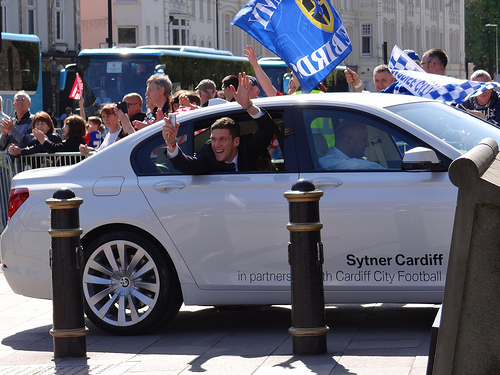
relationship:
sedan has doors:
[1, 93, 500, 335] [130, 99, 306, 292]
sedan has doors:
[1, 93, 500, 335] [301, 102, 460, 292]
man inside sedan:
[162, 71, 289, 176] [1, 93, 500, 335]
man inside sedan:
[318, 119, 389, 171] [1, 93, 500, 335]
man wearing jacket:
[162, 71, 289, 176] [166, 113, 281, 171]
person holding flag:
[243, 43, 303, 96] [229, 0, 354, 96]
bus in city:
[73, 44, 350, 118] [1, 2, 497, 374]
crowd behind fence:
[3, 59, 500, 146] [3, 153, 95, 236]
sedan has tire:
[1, 93, 500, 335] [78, 227, 184, 336]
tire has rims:
[78, 227, 184, 336] [81, 241, 160, 327]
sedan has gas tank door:
[1, 93, 500, 335] [90, 174, 126, 199]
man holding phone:
[162, 71, 289, 176] [166, 112, 176, 128]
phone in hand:
[166, 112, 176, 128] [160, 118, 181, 148]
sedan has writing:
[1, 93, 500, 335] [236, 252, 446, 284]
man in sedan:
[318, 119, 389, 171] [1, 93, 500, 335]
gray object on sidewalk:
[425, 138, 498, 374] [2, 360, 497, 374]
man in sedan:
[162, 71, 289, 176] [1, 93, 500, 335]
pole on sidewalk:
[46, 187, 91, 365] [2, 360, 497, 374]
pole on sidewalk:
[283, 179, 331, 356] [2, 360, 497, 374]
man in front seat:
[318, 119, 389, 171] [310, 134, 332, 159]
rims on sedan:
[81, 241, 160, 327] [1, 93, 500, 335]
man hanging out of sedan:
[162, 71, 289, 176] [1, 93, 500, 335]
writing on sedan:
[236, 252, 446, 284] [1, 93, 500, 335]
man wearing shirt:
[318, 119, 389, 171] [320, 146, 397, 173]